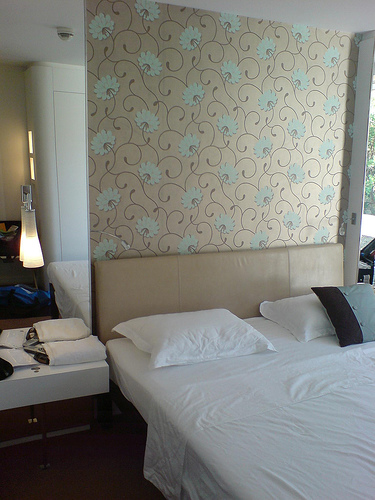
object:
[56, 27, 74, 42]
detector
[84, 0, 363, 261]
wall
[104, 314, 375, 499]
sheets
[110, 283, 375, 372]
pillows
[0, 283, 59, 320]
bag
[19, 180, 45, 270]
light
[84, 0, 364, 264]
wallpaper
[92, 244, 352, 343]
head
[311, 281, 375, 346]
accent pillow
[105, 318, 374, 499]
bed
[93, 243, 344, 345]
headboard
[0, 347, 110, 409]
table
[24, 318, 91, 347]
towel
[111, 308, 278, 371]
pillow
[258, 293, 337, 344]
pillow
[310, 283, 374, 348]
pillow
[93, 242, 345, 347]
board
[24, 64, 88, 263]
reflection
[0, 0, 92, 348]
large mirror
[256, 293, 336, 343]
white pillow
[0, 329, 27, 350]
paper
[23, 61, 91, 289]
cabinet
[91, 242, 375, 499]
bed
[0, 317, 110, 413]
counter